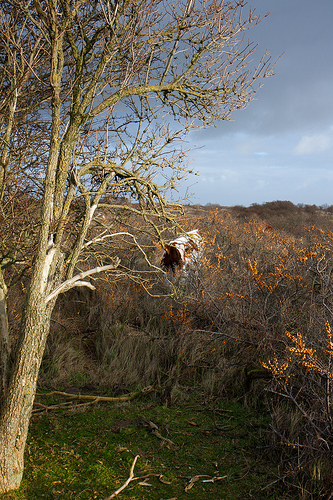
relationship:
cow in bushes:
[159, 226, 204, 277] [4, 183, 321, 491]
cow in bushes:
[159, 226, 204, 277] [9, 175, 306, 497]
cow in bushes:
[159, 226, 204, 277] [140, 259, 239, 320]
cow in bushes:
[159, 226, 204, 277] [137, 251, 232, 317]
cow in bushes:
[159, 226, 204, 277] [141, 234, 234, 308]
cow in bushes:
[159, 226, 204, 277] [175, 241, 234, 308]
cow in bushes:
[159, 226, 204, 277] [156, 237, 237, 320]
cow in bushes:
[159, 226, 204, 277] [169, 238, 226, 304]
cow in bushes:
[159, 226, 204, 277] [177, 244, 226, 300]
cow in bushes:
[159, 226, 204, 277] [174, 236, 226, 295]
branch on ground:
[101, 454, 144, 499] [140, 446, 184, 493]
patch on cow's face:
[167, 236, 186, 258] [149, 236, 184, 275]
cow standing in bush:
[159, 226, 204, 277] [174, 245, 228, 291]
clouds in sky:
[281, 141, 324, 176] [190, 119, 317, 200]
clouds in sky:
[281, 141, 324, 176] [223, 130, 331, 201]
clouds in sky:
[281, 141, 324, 176] [187, 138, 279, 178]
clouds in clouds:
[281, 141, 324, 176] [243, 174, 270, 193]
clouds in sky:
[281, 141, 324, 176] [281, 134, 310, 172]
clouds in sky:
[281, 141, 324, 176] [247, 76, 332, 187]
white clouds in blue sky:
[192, 158, 309, 184] [172, 44, 320, 192]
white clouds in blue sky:
[192, 158, 309, 184] [258, 13, 319, 190]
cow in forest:
[159, 226, 204, 277] [2, 197, 321, 380]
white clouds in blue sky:
[192, 158, 309, 184] [259, 23, 320, 143]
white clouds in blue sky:
[192, 158, 309, 184] [268, 29, 321, 104]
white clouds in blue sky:
[192, 158, 309, 184] [234, 0, 317, 117]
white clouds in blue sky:
[192, 158, 309, 184] [243, 1, 322, 120]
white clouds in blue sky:
[192, 158, 309, 184] [261, 2, 322, 123]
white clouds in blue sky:
[192, 158, 309, 184] [260, 10, 322, 115]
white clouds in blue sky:
[192, 158, 309, 184] [255, 2, 318, 121]